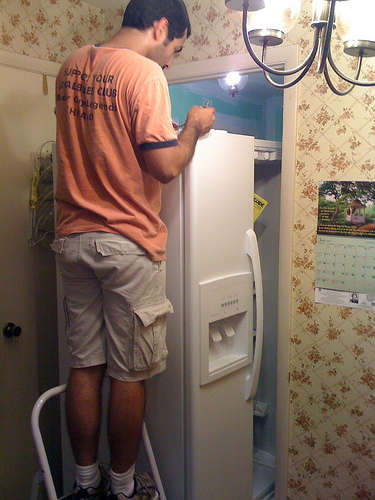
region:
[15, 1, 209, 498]
man standing on a white step stool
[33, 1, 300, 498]
man is working on a white refrigerator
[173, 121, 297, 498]
white refrigerator is stuck in doorway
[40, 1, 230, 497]
man is attempting to remove doors to refrigerator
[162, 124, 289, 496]
refrigerator is missing a door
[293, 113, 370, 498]
beige floral wallpaper on wall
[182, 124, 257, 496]
refrigerator door has ice and water dispenser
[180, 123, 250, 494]
ice and water dispenser in refrigerator door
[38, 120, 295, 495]
white refrigerator with one door is in doorway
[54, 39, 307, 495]
man is working on a white refrigerator that is stuck in doorway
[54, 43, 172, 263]
orange cotton tee shirt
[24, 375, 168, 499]
white metal step stool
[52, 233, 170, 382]
tan khaki cargo shorts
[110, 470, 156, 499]
grey and blue sneaker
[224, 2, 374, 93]
metal lamp on ceiling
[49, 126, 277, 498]
white metal refrigerator freezer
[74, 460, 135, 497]
white cotton tube socks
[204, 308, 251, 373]
ice maker in refrigerator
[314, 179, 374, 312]
calendar hanging on wall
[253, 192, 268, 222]
yellow paper in refrigerator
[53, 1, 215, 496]
a man standing on a stepladder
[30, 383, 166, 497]
a white stepladder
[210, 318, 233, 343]
two white switches on a fridge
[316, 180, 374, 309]
a calendar on a wall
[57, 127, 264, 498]
a white fridge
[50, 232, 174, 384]
man wearing tan shorts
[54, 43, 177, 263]
man wearing a salmon shirt with black borders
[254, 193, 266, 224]
a yellow bit of paper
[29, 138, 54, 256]
wired behind a fridge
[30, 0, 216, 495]
Man standing on a stool.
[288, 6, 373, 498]
Floral wallpaper on a wall.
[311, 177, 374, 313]
Calendar on a wall.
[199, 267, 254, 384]
Refrigerator ice and water dispenser.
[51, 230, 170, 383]
Beige shorts of a man.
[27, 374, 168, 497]
White stool next to a refrigerator.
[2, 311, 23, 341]
Door knob of a door.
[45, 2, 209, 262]
Man wearing an orange shirt.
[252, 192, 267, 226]
Yellow tag on a refrigerator.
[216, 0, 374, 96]
Chandelier in a kitchen.